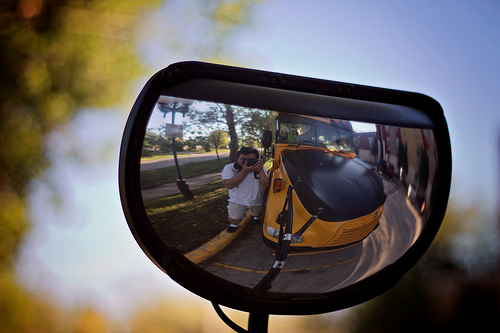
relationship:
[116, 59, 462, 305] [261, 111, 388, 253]
mirror with bus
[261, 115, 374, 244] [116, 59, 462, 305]
bus in a mirror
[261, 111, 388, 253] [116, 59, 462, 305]
bus in a mirror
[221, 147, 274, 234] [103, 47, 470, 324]
adult male in a mirror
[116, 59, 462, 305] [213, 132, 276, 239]
mirror with a man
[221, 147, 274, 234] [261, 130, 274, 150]
adult male in a black mirror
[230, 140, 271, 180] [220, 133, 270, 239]
head of a person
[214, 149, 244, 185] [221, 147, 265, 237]
arm of a person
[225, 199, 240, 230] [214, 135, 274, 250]
leg of a person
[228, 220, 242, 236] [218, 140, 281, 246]
foot of a person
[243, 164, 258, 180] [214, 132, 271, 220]
hand of a person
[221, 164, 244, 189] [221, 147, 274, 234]
arm of a adult male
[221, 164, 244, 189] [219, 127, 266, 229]
arm of a person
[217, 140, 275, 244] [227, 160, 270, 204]
adult male in shirt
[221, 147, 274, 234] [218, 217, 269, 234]
adult male wearing shoes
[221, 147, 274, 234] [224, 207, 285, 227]
adult male wearing shoes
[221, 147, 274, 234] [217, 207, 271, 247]
adult male wearing black shoes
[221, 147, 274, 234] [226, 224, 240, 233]
adult male wearing black shoes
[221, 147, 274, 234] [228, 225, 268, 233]
adult male wearing socks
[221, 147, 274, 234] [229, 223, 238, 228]
adult male wearing man wearing socks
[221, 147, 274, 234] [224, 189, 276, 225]
adult male wearing shorts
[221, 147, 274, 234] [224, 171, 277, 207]
adult male wearing shirt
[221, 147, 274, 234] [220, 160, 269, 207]
adult male wearing shirt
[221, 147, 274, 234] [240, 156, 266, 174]
adult male holding black camera